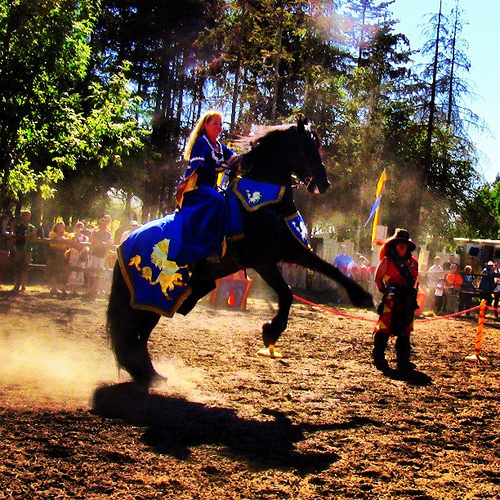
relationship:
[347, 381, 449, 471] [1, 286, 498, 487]
hoof prints in dirt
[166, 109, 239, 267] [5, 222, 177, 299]
girl behind fence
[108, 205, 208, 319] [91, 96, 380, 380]
cloth on horse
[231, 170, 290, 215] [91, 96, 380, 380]
cloth on horse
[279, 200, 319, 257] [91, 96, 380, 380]
cloth on horse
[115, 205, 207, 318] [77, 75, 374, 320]
cloth on horse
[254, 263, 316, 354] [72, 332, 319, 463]
leg in sand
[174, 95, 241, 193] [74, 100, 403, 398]
girl sitting on a horse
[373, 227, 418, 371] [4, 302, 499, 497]
girl standing on ground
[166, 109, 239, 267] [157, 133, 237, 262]
girl in costume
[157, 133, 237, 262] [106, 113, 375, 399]
costume riding black horse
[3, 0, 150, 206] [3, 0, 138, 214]
leaves on tree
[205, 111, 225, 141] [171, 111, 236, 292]
face of girl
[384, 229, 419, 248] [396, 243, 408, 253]
hat on head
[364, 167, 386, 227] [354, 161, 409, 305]
flag on pole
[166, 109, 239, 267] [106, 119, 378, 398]
girl riding black horse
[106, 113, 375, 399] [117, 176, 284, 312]
black horse wearing clothing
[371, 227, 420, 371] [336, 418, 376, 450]
girl standing in dirt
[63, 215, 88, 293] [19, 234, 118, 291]
person standing behind fence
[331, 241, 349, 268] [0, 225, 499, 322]
person standing behind fence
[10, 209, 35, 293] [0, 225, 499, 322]
person standing behind fence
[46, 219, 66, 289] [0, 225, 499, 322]
person standing behind fence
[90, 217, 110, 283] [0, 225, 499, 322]
person standing behind fence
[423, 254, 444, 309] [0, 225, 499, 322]
person standing behind fence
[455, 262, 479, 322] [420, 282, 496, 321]
person standing behind fence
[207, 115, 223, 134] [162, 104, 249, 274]
face of girl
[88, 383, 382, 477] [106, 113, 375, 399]
shadow of black horse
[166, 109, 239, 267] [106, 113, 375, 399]
girl riding black horse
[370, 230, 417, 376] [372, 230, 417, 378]
man in costume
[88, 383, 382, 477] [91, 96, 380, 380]
shadow of horse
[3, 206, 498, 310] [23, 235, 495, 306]
spectators behind fence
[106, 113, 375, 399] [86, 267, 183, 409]
black horse on legs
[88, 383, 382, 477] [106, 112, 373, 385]
shadow cast by horse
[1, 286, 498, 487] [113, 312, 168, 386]
dirt kicked up by horse's feet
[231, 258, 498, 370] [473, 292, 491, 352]
rope attached to pole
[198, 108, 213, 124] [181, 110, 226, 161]
headband in hair